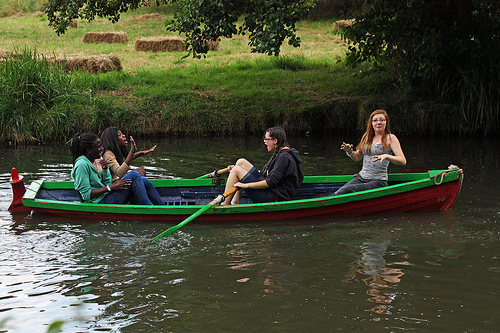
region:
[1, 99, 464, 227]
four women in a row boat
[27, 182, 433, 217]
top frame of boat is green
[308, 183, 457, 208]
bottom of boat is red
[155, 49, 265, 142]
the shore in the background is green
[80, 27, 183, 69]
brown hay stacks on the ground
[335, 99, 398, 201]
woman has red hair and glasses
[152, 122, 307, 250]
woman using oars to row boat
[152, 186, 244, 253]
row boat paddles are green and brown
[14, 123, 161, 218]
two woman sitting on the back of boat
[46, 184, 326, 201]
inside of boat is blue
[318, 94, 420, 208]
a young woman on a boat.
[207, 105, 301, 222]
a person on a boat.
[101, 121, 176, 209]
a woman talking on a boat.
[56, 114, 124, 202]
a girl on the back of a boat.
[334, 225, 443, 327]
a woman's reflection.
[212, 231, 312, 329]
a human reflection on water.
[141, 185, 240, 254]
a green boat paddle.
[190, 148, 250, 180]
a girl holding a paddle.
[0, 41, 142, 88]
a large brown clump of hay.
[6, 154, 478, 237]
a green and brown boat.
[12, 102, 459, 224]
four women in boat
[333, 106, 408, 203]
redheaded woman facing camera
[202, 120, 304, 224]
woman holding two oars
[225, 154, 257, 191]
two bare bent knees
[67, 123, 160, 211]
two women in back of boat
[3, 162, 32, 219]
red rutter on back of boat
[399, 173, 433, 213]
red boat with green trim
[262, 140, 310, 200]
sweatshirt with hood on back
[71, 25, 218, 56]
bales of hay on grass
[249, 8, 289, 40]
green leaves of tree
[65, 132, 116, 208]
a tree in the picture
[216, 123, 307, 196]
a tree in the picture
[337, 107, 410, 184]
a tree in the picture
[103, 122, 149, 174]
a tree in the picture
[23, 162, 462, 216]
this is a raft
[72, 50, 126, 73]
a pile of hay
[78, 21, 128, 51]
a pile of hay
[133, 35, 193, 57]
a pile of hay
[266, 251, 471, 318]
that is water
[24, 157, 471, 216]
the raft is green and yellow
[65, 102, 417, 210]
the people in the canoe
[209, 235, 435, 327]
the reflection in the water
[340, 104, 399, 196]
the red headed girl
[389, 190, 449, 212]
the red on the boat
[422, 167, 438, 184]
the green on the boat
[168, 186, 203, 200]
the blue on the boat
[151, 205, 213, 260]
the green paddle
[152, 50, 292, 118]
the green grass near the water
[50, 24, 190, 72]
the hay bales on the grass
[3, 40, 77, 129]
the long over grown grass